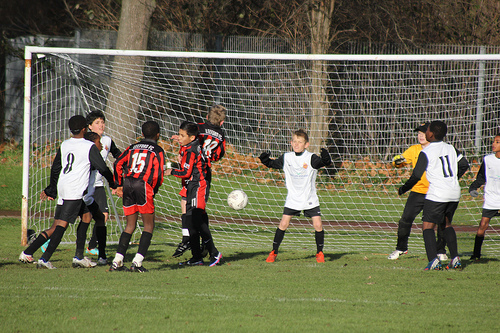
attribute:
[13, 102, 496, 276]
children — boys, playing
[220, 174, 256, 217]
soccer ball — white, flying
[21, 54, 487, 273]
net — white, large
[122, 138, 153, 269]
uniform — red, black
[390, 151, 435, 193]
shirt — yellow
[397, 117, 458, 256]
goalie — upset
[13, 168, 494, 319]
grass — green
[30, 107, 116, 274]
uniform — white, black, long sleeved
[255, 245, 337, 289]
shoes — orange, red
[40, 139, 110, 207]
jersey — white, black, long sleeved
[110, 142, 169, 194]
jersey — orange, black, long sleeved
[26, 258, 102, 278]
cleats — grey, black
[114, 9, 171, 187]
trunk — brown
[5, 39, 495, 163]
fence — wooden, metal, long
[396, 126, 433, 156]
hat — black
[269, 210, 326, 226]
shorts — black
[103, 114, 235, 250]
uniforms — red, black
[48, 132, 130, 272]
uniforms — white, black